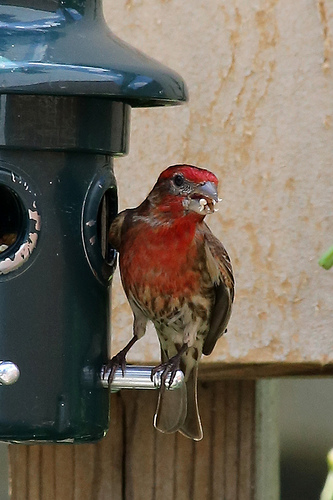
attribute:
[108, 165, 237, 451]
bird — red and brown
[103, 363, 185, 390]
stick — silver 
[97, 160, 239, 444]
bird — small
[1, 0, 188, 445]
feeder — black and silver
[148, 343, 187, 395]
claws — very sharp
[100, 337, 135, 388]
claws — very sharp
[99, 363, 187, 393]
support — wide, shiny, elevated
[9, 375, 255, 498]
fence — brown, wooden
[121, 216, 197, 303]
patch — red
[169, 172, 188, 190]
eye — small, sharp, black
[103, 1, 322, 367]
wall — coarse, tinted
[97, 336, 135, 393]
claw — long, sharp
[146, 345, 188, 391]
claw — long, sharp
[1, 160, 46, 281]
shape — circular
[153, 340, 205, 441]
tail wing — long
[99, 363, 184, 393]
object — shiny, metal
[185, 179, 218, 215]
beak — small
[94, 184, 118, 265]
hole — round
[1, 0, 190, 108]
cover — shiny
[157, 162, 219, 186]
top — red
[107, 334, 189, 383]
feet — brown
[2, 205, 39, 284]
paint — chipped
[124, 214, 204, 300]
chest — red